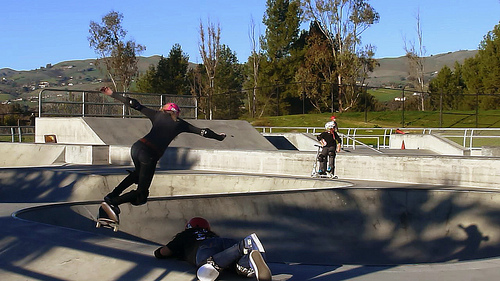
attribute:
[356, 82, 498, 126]
fence — black, chain link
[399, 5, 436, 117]
tree — bare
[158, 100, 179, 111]
helmet — pink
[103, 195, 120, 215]
sneaker — black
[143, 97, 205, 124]
helmet — white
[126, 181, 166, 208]
knee pad — white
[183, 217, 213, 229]
helmet — red